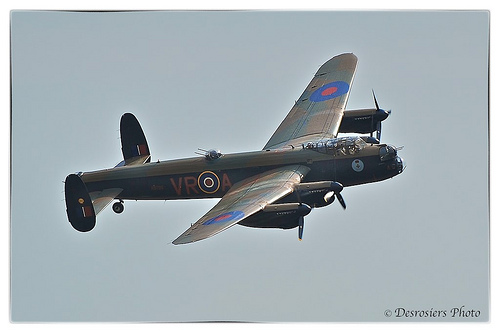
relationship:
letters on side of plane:
[169, 168, 232, 199] [60, 46, 406, 247]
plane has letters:
[60, 46, 406, 247] [169, 168, 232, 199]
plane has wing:
[60, 46, 406, 247] [264, 51, 361, 148]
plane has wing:
[60, 46, 406, 247] [167, 171, 309, 249]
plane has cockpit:
[60, 46, 406, 247] [305, 134, 372, 159]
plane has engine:
[60, 46, 406, 247] [238, 201, 313, 233]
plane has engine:
[60, 46, 406, 247] [280, 179, 347, 210]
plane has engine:
[60, 46, 406, 247] [341, 105, 391, 136]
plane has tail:
[60, 46, 406, 247] [63, 109, 156, 235]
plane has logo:
[60, 46, 406, 247] [196, 169, 221, 195]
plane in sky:
[60, 46, 406, 247] [14, 15, 492, 322]